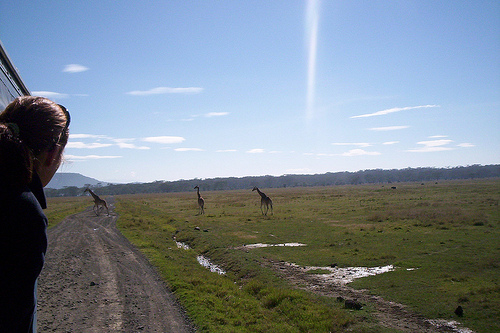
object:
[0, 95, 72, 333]
person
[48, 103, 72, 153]
sunglasses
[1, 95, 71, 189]
head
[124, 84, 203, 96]
clouds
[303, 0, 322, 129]
streak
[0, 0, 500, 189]
sky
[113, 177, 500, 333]
grass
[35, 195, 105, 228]
grass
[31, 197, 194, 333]
road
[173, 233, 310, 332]
ditch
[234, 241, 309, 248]
puddles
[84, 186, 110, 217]
giraffe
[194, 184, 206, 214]
giraffes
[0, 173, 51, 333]
sweater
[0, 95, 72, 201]
hair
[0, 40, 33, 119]
bus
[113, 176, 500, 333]
field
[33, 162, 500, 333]
habitat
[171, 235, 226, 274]
water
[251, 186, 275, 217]
giraffe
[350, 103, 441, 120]
cloud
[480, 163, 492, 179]
trees